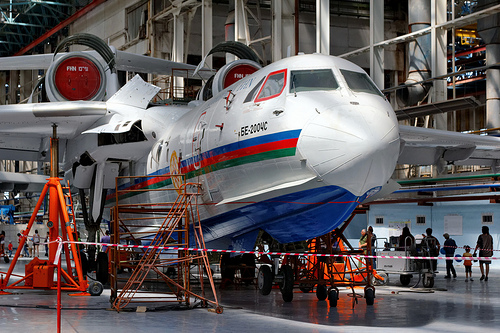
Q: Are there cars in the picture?
A: No, there are no cars.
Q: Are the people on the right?
A: Yes, the people are on the right of the image.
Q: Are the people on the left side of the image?
A: No, the people are on the right of the image.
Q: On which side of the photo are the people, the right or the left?
A: The people are on the right of the image.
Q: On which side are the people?
A: The people are on the right of the image.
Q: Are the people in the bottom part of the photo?
A: Yes, the people are in the bottom of the image.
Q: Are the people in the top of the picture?
A: No, the people are in the bottom of the image.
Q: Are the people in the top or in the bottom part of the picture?
A: The people are in the bottom of the image.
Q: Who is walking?
A: The people are walking.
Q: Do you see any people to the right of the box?
A: Yes, there are people to the right of the box.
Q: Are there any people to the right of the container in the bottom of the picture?
A: Yes, there are people to the right of the box.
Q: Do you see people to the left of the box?
A: No, the people are to the right of the box.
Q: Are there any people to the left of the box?
A: No, the people are to the right of the box.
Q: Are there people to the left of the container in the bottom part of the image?
A: No, the people are to the right of the box.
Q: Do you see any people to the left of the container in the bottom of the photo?
A: No, the people are to the right of the box.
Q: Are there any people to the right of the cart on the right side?
A: Yes, there are people to the right of the cart.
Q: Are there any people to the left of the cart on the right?
A: No, the people are to the right of the cart.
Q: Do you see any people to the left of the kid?
A: Yes, there are people to the left of the kid.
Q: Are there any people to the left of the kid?
A: Yes, there are people to the left of the kid.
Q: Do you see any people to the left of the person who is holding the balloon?
A: Yes, there are people to the left of the kid.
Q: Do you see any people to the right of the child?
A: No, the people are to the left of the child.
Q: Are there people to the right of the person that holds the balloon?
A: No, the people are to the left of the child.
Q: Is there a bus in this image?
A: No, there are no buses.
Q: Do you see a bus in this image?
A: No, there are no buses.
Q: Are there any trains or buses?
A: No, there are no buses or trains.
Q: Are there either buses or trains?
A: No, there are no buses or trains.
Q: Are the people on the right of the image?
A: Yes, the people are on the right of the image.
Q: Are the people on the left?
A: No, the people are on the right of the image.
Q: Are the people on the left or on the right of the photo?
A: The people are on the right of the image.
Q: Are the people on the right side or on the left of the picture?
A: The people are on the right of the image.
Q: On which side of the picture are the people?
A: The people are on the right of the image.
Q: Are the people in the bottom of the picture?
A: Yes, the people are in the bottom of the image.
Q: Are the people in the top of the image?
A: No, the people are in the bottom of the image.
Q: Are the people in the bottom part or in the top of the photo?
A: The people are in the bottom of the image.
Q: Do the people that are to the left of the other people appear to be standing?
A: Yes, the people are standing.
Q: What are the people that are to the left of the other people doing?
A: The people are standing.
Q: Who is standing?
A: The people are standing.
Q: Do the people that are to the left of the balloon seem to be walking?
A: No, the people are standing.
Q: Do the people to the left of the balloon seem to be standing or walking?
A: The people are standing.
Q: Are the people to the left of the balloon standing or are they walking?
A: The people are standing.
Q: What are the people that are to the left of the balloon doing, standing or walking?
A: The people are standing.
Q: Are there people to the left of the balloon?
A: Yes, there are people to the left of the balloon.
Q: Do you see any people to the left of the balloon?
A: Yes, there are people to the left of the balloon.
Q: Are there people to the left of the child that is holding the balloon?
A: Yes, there are people to the left of the kid.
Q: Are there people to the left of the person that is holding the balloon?
A: Yes, there are people to the left of the kid.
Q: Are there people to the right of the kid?
A: No, the people are to the left of the kid.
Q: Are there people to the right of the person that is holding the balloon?
A: No, the people are to the left of the kid.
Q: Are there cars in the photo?
A: No, there are no cars.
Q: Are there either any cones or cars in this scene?
A: No, there are no cars or cones.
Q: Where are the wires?
A: The wires are on the floor.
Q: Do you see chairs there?
A: No, there are no chairs.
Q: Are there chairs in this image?
A: No, there are no chairs.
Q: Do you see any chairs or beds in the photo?
A: No, there are no chairs or beds.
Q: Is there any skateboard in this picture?
A: No, there are no skateboards.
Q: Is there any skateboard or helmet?
A: No, there are no skateboards or helmets.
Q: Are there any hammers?
A: No, there are no hammers.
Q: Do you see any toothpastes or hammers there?
A: No, there are no hammers or toothpastes.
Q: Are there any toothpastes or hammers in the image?
A: No, there are no hammers or toothpastes.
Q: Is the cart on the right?
A: Yes, the cart is on the right of the image.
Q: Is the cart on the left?
A: No, the cart is on the right of the image.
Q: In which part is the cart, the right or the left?
A: The cart is on the right of the image.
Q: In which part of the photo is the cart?
A: The cart is on the right of the image.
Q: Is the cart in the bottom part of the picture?
A: Yes, the cart is in the bottom of the image.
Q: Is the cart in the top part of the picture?
A: No, the cart is in the bottom of the image.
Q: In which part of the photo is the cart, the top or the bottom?
A: The cart is in the bottom of the image.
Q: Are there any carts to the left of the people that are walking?
A: Yes, there is a cart to the left of the people.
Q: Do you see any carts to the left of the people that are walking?
A: Yes, there is a cart to the left of the people.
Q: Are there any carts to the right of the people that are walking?
A: No, the cart is to the left of the people.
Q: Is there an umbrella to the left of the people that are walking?
A: No, there is a cart to the left of the people.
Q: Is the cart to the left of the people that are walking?
A: Yes, the cart is to the left of the people.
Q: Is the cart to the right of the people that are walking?
A: No, the cart is to the left of the people.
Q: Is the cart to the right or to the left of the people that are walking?
A: The cart is to the left of the people.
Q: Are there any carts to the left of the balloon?
A: Yes, there is a cart to the left of the balloon.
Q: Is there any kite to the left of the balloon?
A: No, there is a cart to the left of the balloon.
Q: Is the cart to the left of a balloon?
A: Yes, the cart is to the left of a balloon.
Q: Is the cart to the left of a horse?
A: No, the cart is to the left of a balloon.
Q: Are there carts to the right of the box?
A: Yes, there is a cart to the right of the box.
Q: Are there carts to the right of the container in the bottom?
A: Yes, there is a cart to the right of the box.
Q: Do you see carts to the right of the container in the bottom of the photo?
A: Yes, there is a cart to the right of the box.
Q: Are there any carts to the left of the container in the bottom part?
A: No, the cart is to the right of the box.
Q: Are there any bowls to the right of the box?
A: No, there is a cart to the right of the box.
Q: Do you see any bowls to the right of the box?
A: No, there is a cart to the right of the box.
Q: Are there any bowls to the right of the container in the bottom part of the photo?
A: No, there is a cart to the right of the box.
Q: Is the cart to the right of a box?
A: Yes, the cart is to the right of a box.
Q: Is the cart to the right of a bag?
A: No, the cart is to the right of a box.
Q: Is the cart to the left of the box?
A: No, the cart is to the right of the box.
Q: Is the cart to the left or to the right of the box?
A: The cart is to the right of the box.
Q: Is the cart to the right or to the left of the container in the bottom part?
A: The cart is to the right of the box.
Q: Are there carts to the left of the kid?
A: Yes, there is a cart to the left of the kid.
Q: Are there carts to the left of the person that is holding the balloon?
A: Yes, there is a cart to the left of the kid.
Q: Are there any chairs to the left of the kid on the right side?
A: No, there is a cart to the left of the child.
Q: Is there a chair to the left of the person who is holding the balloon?
A: No, there is a cart to the left of the child.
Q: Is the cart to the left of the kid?
A: Yes, the cart is to the left of the kid.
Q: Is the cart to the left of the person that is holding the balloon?
A: Yes, the cart is to the left of the kid.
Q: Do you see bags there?
A: No, there are no bags.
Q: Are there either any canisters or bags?
A: No, there are no bags or canisters.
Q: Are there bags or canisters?
A: No, there are no bags or canisters.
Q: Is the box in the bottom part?
A: Yes, the box is in the bottom of the image.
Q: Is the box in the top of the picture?
A: No, the box is in the bottom of the image.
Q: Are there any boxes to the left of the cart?
A: Yes, there is a box to the left of the cart.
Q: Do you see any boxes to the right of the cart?
A: No, the box is to the left of the cart.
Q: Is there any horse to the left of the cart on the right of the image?
A: No, there is a box to the left of the cart.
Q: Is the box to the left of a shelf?
A: No, the box is to the left of a cart.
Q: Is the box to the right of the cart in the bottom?
A: No, the box is to the left of the cart.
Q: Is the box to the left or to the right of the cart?
A: The box is to the left of the cart.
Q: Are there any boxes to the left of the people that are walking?
A: Yes, there is a box to the left of the people.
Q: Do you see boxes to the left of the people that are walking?
A: Yes, there is a box to the left of the people.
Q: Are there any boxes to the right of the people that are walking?
A: No, the box is to the left of the people.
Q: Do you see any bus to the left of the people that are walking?
A: No, there is a box to the left of the people.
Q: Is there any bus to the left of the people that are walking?
A: No, there is a box to the left of the people.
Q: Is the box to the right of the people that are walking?
A: No, the box is to the left of the people.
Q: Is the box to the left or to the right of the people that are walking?
A: The box is to the left of the people.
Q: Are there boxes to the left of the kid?
A: Yes, there is a box to the left of the kid.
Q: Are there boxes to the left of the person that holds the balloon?
A: Yes, there is a box to the left of the kid.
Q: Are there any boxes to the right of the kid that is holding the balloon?
A: No, the box is to the left of the kid.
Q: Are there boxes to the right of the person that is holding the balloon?
A: No, the box is to the left of the kid.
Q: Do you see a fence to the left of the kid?
A: No, there is a box to the left of the kid.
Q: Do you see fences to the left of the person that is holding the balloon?
A: No, there is a box to the left of the kid.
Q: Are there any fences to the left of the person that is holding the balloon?
A: No, there is a box to the left of the kid.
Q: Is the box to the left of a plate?
A: No, the box is to the left of the child.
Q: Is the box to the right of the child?
A: No, the box is to the left of the child.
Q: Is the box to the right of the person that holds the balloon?
A: No, the box is to the left of the child.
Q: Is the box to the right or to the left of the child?
A: The box is to the left of the child.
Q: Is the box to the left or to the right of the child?
A: The box is to the left of the child.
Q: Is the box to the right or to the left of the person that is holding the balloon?
A: The box is to the left of the child.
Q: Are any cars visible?
A: No, there are no cars.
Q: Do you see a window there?
A: Yes, there is a window.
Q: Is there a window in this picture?
A: Yes, there is a window.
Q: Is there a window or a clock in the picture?
A: Yes, there is a window.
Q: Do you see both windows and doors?
A: Yes, there are both a window and a door.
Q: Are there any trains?
A: No, there are no trains.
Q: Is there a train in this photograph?
A: No, there are no trains.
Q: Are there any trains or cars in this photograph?
A: No, there are no trains or cars.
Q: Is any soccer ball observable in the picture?
A: No, there are no soccer balls.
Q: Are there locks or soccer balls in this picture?
A: No, there are no soccer balls or locks.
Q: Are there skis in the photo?
A: No, there are no skis.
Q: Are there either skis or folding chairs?
A: No, there are no skis or folding chairs.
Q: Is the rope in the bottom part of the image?
A: Yes, the rope is in the bottom of the image.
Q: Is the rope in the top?
A: No, the rope is in the bottom of the image.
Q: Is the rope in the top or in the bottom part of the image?
A: The rope is in the bottom of the image.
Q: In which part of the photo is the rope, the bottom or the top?
A: The rope is in the bottom of the image.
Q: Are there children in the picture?
A: Yes, there is a child.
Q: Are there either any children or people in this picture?
A: Yes, there is a child.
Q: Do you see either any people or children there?
A: Yes, there is a child.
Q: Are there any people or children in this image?
A: Yes, there is a child.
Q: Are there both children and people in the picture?
A: Yes, there are both a child and a person.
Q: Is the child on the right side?
A: Yes, the child is on the right of the image.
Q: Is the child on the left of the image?
A: No, the child is on the right of the image.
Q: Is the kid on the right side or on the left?
A: The kid is on the right of the image.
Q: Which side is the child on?
A: The child is on the right of the image.